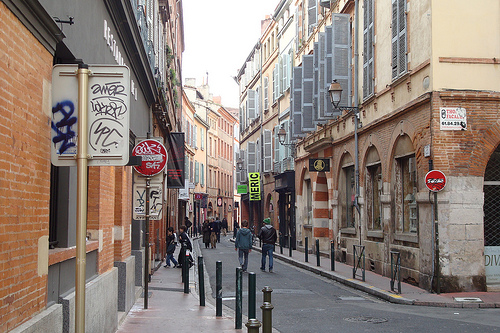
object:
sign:
[248, 170, 261, 201]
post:
[182, 254, 190, 296]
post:
[247, 271, 254, 321]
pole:
[196, 252, 206, 307]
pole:
[214, 258, 223, 319]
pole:
[233, 266, 240, 333]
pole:
[246, 269, 253, 320]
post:
[316, 238, 320, 265]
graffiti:
[46, 61, 132, 166]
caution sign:
[424, 170, 446, 193]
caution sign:
[131, 139, 168, 177]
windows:
[234, 16, 375, 193]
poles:
[261, 301, 275, 333]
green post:
[247, 272, 256, 330]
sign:
[424, 169, 447, 192]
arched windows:
[332, 132, 418, 249]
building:
[313, 0, 499, 299]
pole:
[70, 63, 92, 328]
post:
[290, 235, 293, 256]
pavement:
[274, 258, 343, 331]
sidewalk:
[129, 194, 500, 332]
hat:
[263, 217, 271, 224]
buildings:
[0, 0, 499, 332]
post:
[304, 236, 308, 262]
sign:
[131, 139, 168, 176]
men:
[260, 217, 278, 272]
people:
[164, 225, 193, 269]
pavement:
[114, 308, 242, 333]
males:
[235, 219, 252, 273]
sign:
[45, 63, 130, 166]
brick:
[6, 215, 21, 229]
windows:
[48, 42, 91, 253]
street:
[197, 214, 495, 333]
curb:
[271, 245, 493, 327]